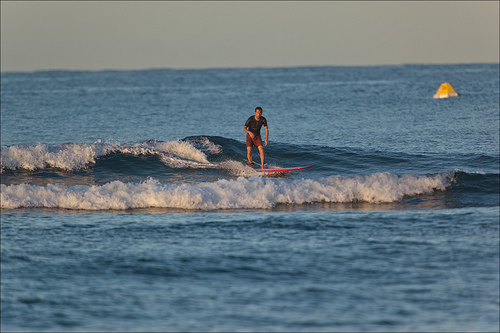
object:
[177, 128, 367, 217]
light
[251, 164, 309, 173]
surfboard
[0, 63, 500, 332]
water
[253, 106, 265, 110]
hair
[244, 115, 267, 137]
shirt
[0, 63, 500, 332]
ripples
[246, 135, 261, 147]
trunks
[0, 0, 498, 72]
sky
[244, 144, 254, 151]
knees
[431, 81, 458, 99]
buoy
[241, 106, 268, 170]
surfer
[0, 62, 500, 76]
horizon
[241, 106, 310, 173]
sport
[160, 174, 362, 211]
reflection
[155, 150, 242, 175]
wake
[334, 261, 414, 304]
part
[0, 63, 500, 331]
blue water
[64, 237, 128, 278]
part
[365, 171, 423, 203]
part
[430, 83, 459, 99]
yellow boat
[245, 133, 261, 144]
brown shorts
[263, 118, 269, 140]
arm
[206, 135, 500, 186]
shadow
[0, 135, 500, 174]
waves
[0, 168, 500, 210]
wave